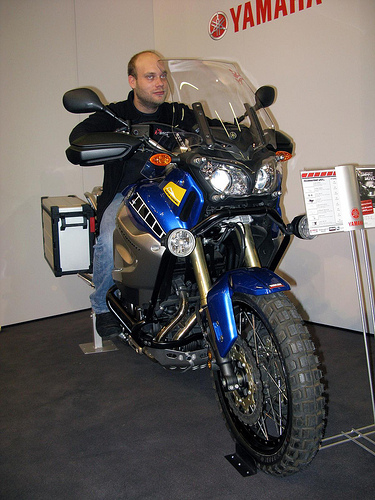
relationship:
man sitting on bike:
[67, 48, 289, 341] [32, 59, 346, 487]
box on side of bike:
[39, 196, 93, 274] [37, 87, 328, 479]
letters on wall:
[229, 0, 328, 33] [156, 3, 374, 331]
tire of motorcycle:
[208, 272, 325, 482] [81, 183, 319, 391]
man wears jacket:
[67, 48, 290, 341] [62, 89, 224, 238]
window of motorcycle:
[163, 56, 277, 138] [38, 55, 330, 479]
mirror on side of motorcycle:
[60, 88, 141, 135] [38, 55, 330, 479]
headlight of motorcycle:
[252, 155, 283, 193] [56, 82, 330, 474]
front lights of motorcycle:
[208, 165, 248, 194] [56, 82, 330, 474]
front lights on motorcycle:
[208, 165, 248, 194] [56, 82, 330, 474]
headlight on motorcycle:
[252, 158, 282, 192] [56, 82, 330, 474]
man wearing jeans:
[67, 48, 290, 341] [103, 177, 145, 331]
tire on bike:
[208, 272, 328, 481] [41, 59, 325, 478]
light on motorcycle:
[163, 227, 196, 258] [56, 82, 330, 474]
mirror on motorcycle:
[255, 86, 275, 109] [56, 82, 330, 474]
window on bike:
[163, 56, 283, 154] [41, 59, 325, 478]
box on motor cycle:
[41, 195, 94, 276] [40, 86, 326, 477]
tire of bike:
[208, 272, 325, 482] [32, 59, 346, 487]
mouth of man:
[149, 86, 166, 99] [106, 63, 165, 109]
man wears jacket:
[67, 48, 289, 341] [67, 88, 283, 201]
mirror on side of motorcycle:
[253, 83, 277, 109] [38, 55, 330, 479]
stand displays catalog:
[286, 157, 373, 412] [294, 159, 362, 237]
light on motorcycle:
[167, 227, 196, 258] [38, 55, 330, 479]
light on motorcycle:
[286, 209, 324, 245] [38, 55, 330, 479]